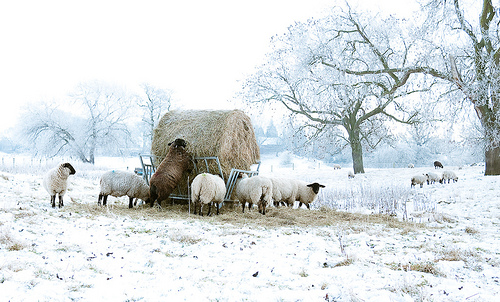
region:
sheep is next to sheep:
[39, 164, 76, 210]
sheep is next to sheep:
[96, 170, 150, 207]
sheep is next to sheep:
[148, 139, 192, 209]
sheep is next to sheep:
[190, 169, 225, 217]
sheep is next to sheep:
[234, 172, 273, 214]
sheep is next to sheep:
[266, 175, 296, 205]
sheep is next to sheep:
[287, 180, 324, 212]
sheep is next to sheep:
[407, 171, 427, 186]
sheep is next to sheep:
[426, 167, 442, 182]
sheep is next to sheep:
[443, 170, 458, 182]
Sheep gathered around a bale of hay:
[44, 135, 331, 217]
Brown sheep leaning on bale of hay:
[145, 134, 197, 209]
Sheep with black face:
[305, 175, 325, 193]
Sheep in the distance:
[405, 155, 459, 187]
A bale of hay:
[146, 99, 261, 191]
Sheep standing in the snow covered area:
[36, 136, 331, 222]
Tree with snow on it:
[265, 10, 413, 183]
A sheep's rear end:
[247, 171, 272, 210]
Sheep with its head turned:
[46, 155, 78, 202]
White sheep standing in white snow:
[37, 126, 336, 219]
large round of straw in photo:
[168, 99, 262, 160]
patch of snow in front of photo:
[181, 246, 225, 298]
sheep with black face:
[306, 176, 327, 208]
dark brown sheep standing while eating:
[158, 130, 195, 218]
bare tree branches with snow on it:
[283, 37, 325, 90]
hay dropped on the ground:
[296, 212, 357, 218]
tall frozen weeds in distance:
[352, 174, 409, 219]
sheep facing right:
[49, 140, 79, 200]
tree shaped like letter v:
[41, 106, 116, 178]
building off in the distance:
[262, 113, 280, 161]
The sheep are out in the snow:
[10, 17, 481, 265]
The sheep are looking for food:
[10, 26, 470, 261]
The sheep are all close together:
[15, 35, 356, 285]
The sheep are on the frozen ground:
[35, 35, 371, 272]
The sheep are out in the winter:
[30, 38, 371, 274]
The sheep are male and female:
[20, 40, 376, 275]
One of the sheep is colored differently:
[35, 66, 350, 281]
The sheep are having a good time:
[26, 47, 381, 273]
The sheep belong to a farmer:
[7, 48, 364, 273]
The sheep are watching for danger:
[21, 38, 366, 271]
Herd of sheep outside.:
[42, 154, 464, 232]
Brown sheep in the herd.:
[145, 131, 191, 215]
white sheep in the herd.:
[189, 168, 226, 217]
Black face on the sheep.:
[304, 180, 326, 196]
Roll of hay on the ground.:
[149, 104, 261, 197]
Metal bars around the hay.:
[132, 148, 263, 203]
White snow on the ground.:
[0, 150, 499, 300]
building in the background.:
[252, 115, 286, 152]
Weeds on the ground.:
[322, 174, 434, 224]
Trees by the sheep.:
[242, 8, 498, 192]